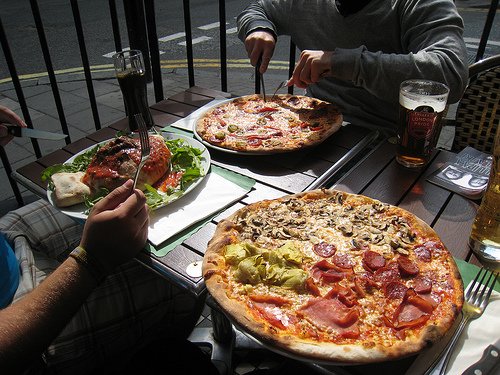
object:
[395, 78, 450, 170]
glass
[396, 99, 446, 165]
beer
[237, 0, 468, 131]
jacket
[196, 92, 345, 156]
pizza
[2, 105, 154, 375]
person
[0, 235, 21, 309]
shirt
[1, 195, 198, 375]
shorts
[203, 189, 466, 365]
pizza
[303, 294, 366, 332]
ham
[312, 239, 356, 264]
pepperoni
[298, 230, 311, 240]
mushrooms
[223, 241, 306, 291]
artichokes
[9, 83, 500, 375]
table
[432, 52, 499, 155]
chair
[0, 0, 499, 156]
fence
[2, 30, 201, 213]
sidewalk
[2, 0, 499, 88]
street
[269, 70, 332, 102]
fork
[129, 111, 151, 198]
fork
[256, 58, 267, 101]
knife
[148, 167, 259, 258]
placemat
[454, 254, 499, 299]
placemat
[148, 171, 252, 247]
napkin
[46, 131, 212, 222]
plate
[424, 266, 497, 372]
fork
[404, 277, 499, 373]
napkin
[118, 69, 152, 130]
beer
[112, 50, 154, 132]
glass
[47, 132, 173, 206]
meal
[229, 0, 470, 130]
people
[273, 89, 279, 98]
tines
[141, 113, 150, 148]
tines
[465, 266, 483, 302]
tines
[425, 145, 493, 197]
magazine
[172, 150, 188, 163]
lettuce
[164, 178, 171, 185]
tomato sauce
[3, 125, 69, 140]
knife